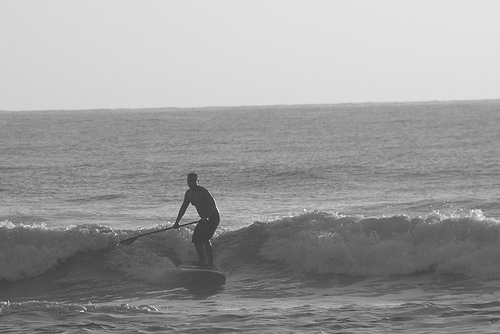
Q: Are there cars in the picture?
A: No, there are no cars.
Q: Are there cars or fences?
A: No, there are no cars or fences.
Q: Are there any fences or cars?
A: No, there are no cars or fences.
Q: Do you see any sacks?
A: No, there are no sacks.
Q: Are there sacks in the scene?
A: No, there are no sacks.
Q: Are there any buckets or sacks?
A: No, there are no sacks or buckets.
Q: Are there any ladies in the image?
A: No, there are no ladies.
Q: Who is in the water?
A: The man is in the water.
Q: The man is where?
A: The man is in the water.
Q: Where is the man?
A: The man is in the water.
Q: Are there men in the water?
A: Yes, there is a man in the water.